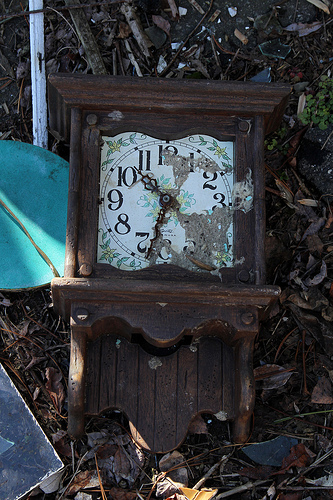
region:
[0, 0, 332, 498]
the clock is on leaves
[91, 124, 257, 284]
the clock is broken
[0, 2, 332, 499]
the leaves are brown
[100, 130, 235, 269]
the clock has a floral pattern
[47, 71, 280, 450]
the clock is made of wood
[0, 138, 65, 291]
a turqoise object on the ground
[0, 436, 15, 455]
a piece of glass on the ground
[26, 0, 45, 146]
a piece of wood painted white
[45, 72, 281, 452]
the wood clock is worn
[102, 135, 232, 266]
the clock has a white face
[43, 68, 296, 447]
brown wooden clock in forest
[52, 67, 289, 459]
white face of brown clock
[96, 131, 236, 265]
white face with black numbers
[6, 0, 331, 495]
brown dead leaves in forest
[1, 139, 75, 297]
round dirty teal plate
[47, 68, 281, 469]
brown shelf below clock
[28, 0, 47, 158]
white pole on brown leaves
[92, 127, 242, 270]
time reads 10:35 in black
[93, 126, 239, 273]
yellow flowers on white face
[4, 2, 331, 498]
brown branches and brown leaves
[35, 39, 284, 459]
Old clock on dry leaves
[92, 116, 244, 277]
Clock has dirty on surface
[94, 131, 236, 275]
Clock is white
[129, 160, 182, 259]
Clock arms point to 10:38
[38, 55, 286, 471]
Wooden support of clock is damaged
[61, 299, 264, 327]
Two metal bolts in front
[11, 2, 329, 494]
Dry leaves behind clock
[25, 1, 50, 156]
white stick behind a turquoise board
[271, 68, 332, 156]
Green leaves cumming out dry leaves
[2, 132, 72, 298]
Turquoise board behind clock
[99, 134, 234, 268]
this is a clock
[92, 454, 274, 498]
dry leaves shed off a tree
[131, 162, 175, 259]
arms of a clock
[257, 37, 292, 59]
broken piece of a glass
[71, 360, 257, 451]
wooden stand of the clock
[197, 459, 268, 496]
broken branches of the tree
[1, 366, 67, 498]
part of a broken glass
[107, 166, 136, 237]
numbers on the clock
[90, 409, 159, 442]
curve design on the clock stand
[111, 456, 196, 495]
part of the earth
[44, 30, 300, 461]
discarded clock in wooden frame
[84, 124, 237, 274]
flowers decorating corners of clock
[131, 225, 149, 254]
the number seven written in a curly style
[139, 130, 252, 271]
thick web-like material covering the clock face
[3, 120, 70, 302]
round blue object partially hidden by clock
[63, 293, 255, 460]
curves in wood case supporting clock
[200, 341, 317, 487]
twigs, shards and dried leaves surrounding clock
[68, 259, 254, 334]
wooden pegs holding clock frame together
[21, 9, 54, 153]
thin piece of wood molding painted white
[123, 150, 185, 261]
black and dainty clock hands